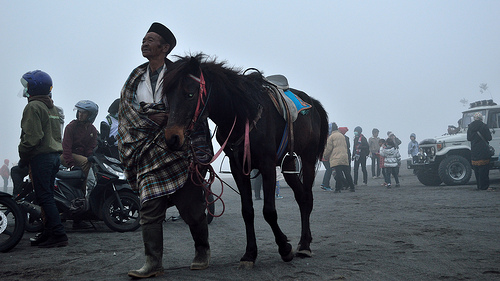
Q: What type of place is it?
A: It is a beach.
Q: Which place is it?
A: It is a beach.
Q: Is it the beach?
A: Yes, it is the beach.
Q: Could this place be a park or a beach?
A: It is a beach.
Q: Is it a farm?
A: No, it is a beach.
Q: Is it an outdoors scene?
A: Yes, it is outdoors.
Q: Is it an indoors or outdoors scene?
A: It is outdoors.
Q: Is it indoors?
A: No, it is outdoors.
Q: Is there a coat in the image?
A: Yes, there is a coat.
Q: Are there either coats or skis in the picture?
A: Yes, there is a coat.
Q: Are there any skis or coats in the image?
A: Yes, there is a coat.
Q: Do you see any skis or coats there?
A: Yes, there is a coat.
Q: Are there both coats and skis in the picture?
A: No, there is a coat but no skis.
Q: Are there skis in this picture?
A: No, there are no skis.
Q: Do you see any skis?
A: No, there are no skis.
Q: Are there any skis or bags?
A: No, there are no skis or bags.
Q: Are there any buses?
A: No, there are no buses.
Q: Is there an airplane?
A: No, there are no airplanes.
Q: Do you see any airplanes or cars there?
A: No, there are no airplanes or cars.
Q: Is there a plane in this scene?
A: No, there are no airplanes.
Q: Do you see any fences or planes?
A: No, there are no planes or fences.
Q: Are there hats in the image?
A: Yes, there is a hat.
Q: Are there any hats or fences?
A: Yes, there is a hat.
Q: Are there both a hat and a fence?
A: No, there is a hat but no fences.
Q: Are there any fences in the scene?
A: No, there are no fences.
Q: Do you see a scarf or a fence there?
A: No, there are no fences or scarves.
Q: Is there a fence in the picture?
A: No, there are no fences.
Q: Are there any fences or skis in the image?
A: No, there are no fences or skis.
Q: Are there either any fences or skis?
A: No, there are no skis or fences.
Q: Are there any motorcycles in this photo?
A: Yes, there is a motorcycle.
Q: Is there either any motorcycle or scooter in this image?
A: Yes, there is a motorcycle.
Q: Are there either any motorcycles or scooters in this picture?
A: Yes, there is a motorcycle.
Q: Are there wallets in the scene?
A: No, there are no wallets.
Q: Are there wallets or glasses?
A: No, there are no wallets or glasses.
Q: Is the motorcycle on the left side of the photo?
A: Yes, the motorcycle is on the left of the image.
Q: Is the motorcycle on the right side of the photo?
A: No, the motorcycle is on the left of the image.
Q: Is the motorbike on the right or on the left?
A: The motorbike is on the left of the image.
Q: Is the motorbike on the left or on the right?
A: The motorbike is on the left of the image.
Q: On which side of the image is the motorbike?
A: The motorbike is on the left of the image.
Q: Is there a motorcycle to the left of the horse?
A: Yes, there is a motorcycle to the left of the horse.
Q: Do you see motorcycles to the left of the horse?
A: Yes, there is a motorcycle to the left of the horse.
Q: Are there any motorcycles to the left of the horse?
A: Yes, there is a motorcycle to the left of the horse.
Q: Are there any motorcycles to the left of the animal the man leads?
A: Yes, there is a motorcycle to the left of the horse.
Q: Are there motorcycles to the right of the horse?
A: No, the motorcycle is to the left of the horse.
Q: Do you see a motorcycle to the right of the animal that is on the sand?
A: No, the motorcycle is to the left of the horse.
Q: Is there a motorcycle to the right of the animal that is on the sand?
A: No, the motorcycle is to the left of the horse.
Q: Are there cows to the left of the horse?
A: No, there is a motorcycle to the left of the horse.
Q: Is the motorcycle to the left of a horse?
A: Yes, the motorcycle is to the left of a horse.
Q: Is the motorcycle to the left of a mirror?
A: No, the motorcycle is to the left of a horse.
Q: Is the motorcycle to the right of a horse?
A: No, the motorcycle is to the left of a horse.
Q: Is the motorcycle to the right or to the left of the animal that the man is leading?
A: The motorcycle is to the left of the horse.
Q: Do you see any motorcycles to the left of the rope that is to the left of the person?
A: Yes, there is a motorcycle to the left of the rope.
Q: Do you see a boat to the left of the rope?
A: No, there is a motorcycle to the left of the rope.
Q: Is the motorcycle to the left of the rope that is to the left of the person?
A: Yes, the motorcycle is to the left of the rope.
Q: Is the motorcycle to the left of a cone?
A: No, the motorcycle is to the left of the rope.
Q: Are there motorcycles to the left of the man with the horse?
A: Yes, there is a motorcycle to the left of the man.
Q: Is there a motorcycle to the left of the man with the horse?
A: Yes, there is a motorcycle to the left of the man.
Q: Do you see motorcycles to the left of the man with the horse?
A: Yes, there is a motorcycle to the left of the man.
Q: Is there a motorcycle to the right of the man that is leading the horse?
A: No, the motorcycle is to the left of the man.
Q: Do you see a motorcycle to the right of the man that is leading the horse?
A: No, the motorcycle is to the left of the man.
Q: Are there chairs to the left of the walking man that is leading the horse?
A: No, there is a motorcycle to the left of the man.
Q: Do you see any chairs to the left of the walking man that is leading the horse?
A: No, there is a motorcycle to the left of the man.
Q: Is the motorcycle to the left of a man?
A: Yes, the motorcycle is to the left of a man.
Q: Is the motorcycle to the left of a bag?
A: No, the motorcycle is to the left of a man.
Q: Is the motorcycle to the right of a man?
A: No, the motorcycle is to the left of a man.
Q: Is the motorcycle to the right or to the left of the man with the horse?
A: The motorcycle is to the left of the man.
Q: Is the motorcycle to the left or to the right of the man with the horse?
A: The motorcycle is to the left of the man.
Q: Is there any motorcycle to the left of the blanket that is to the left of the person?
A: Yes, there is a motorcycle to the left of the blanket.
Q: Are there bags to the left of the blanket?
A: No, there is a motorcycle to the left of the blanket.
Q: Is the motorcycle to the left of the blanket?
A: Yes, the motorcycle is to the left of the blanket.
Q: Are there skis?
A: No, there are no skis.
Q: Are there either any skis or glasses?
A: No, there are no skis or glasses.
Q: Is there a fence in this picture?
A: No, there are no fences.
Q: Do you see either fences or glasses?
A: No, there are no fences or glasses.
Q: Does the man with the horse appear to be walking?
A: Yes, the man is walking.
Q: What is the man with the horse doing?
A: The man is walking.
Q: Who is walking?
A: The man is walking.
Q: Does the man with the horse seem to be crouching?
A: No, the man is walking.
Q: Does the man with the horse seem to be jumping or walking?
A: The man is walking.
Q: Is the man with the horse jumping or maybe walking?
A: The man is walking.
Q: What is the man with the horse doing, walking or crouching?
A: The man is walking.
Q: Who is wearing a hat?
A: The man is wearing a hat.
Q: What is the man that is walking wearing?
A: The man is wearing a hat.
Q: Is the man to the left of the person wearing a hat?
A: Yes, the man is wearing a hat.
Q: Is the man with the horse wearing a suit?
A: No, the man is wearing a hat.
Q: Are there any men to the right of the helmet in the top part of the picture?
A: Yes, there is a man to the right of the helmet.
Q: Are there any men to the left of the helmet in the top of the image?
A: No, the man is to the right of the helmet.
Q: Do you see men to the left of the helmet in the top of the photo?
A: No, the man is to the right of the helmet.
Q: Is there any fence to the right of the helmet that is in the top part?
A: No, there is a man to the right of the helmet.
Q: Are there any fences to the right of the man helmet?
A: No, there is a man to the right of the helmet.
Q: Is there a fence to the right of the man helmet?
A: No, there is a man to the right of the helmet.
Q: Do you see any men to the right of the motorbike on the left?
A: Yes, there is a man to the right of the motorcycle.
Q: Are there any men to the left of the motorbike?
A: No, the man is to the right of the motorbike.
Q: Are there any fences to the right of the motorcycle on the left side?
A: No, there is a man to the right of the motorcycle.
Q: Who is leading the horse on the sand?
A: The man is leading the horse.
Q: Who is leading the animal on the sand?
A: The man is leading the horse.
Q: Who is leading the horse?
A: The man is leading the horse.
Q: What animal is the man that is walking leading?
A: The man is leading the horse.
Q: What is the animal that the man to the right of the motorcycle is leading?
A: The animal is a horse.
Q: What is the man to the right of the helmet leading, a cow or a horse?
A: The man is leading a horse.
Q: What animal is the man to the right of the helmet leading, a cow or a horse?
A: The man is leading a horse.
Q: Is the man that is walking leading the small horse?
A: Yes, the man is leading the horse.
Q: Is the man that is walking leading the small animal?
A: Yes, the man is leading the horse.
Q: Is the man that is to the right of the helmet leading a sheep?
A: No, the man is leading the horse.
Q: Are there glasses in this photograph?
A: No, there are no glasses.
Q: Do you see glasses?
A: No, there are no glasses.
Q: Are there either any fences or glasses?
A: No, there are no glasses or fences.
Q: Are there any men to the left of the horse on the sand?
A: Yes, there is a man to the left of the horse.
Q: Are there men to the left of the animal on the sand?
A: Yes, there is a man to the left of the horse.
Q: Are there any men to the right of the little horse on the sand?
A: No, the man is to the left of the horse.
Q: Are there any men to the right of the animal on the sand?
A: No, the man is to the left of the horse.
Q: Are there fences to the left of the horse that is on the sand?
A: No, there is a man to the left of the horse.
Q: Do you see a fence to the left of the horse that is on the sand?
A: No, there is a man to the left of the horse.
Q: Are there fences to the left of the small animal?
A: No, there is a man to the left of the horse.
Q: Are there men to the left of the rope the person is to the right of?
A: Yes, there is a man to the left of the rope.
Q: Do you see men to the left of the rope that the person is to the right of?
A: Yes, there is a man to the left of the rope.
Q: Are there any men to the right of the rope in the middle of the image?
A: No, the man is to the left of the rope.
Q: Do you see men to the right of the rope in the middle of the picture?
A: No, the man is to the left of the rope.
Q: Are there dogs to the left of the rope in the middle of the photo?
A: No, there is a man to the left of the rope.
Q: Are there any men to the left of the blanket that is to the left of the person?
A: Yes, there is a man to the left of the blanket.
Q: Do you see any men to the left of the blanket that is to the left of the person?
A: Yes, there is a man to the left of the blanket.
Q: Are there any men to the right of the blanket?
A: No, the man is to the left of the blanket.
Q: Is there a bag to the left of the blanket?
A: No, there is a man to the left of the blanket.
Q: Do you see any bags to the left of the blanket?
A: No, there is a man to the left of the blanket.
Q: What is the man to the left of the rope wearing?
A: The man is wearing a helmet.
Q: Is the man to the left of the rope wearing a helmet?
A: Yes, the man is wearing a helmet.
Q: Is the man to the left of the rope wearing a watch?
A: No, the man is wearing a helmet.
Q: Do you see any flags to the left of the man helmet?
A: No, there is a man to the left of the helmet.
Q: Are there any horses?
A: Yes, there is a horse.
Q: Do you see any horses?
A: Yes, there is a horse.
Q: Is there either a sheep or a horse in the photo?
A: Yes, there is a horse.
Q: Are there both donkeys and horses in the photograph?
A: No, there is a horse but no donkeys.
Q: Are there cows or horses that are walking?
A: Yes, the horse is walking.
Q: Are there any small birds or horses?
A: Yes, there is a small horse.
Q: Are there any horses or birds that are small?
A: Yes, the horse is small.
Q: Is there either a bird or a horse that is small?
A: Yes, the horse is small.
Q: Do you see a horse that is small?
A: Yes, there is a small horse.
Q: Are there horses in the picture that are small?
A: Yes, there is a horse that is small.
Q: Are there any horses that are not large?
A: Yes, there is a small horse.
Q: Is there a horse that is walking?
A: Yes, there is a horse that is walking.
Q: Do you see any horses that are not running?
A: Yes, there is a horse that is walking .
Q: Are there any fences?
A: No, there are no fences.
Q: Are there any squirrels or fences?
A: No, there are no fences or squirrels.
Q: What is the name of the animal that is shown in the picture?
A: The animal is a horse.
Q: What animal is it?
A: The animal is a horse.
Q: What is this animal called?
A: This is a horse.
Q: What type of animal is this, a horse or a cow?
A: This is a horse.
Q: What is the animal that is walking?
A: The animal is a horse.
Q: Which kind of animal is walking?
A: The animal is a horse.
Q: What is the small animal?
A: The animal is a horse.